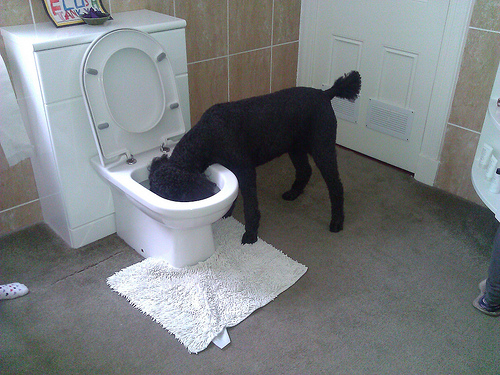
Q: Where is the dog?
A: In bathroom.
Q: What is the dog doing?
A: Drinking.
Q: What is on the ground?
A: Towel.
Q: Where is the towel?
A: On the ground.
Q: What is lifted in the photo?
A: The seat.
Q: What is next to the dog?
A: Door.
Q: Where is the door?
A: Near the dog.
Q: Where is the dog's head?
A: In the toilet.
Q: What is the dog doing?
A: Drinking.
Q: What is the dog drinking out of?
A: Toilet.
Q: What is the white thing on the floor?
A: Rug.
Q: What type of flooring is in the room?
A: Carpet.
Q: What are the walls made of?
A: Tile.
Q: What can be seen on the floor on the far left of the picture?
A: Foot.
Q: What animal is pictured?
A: Dog.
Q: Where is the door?
A: Behind the dog.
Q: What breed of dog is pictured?
A: Poodle.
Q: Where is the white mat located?
A: In front of the toilet.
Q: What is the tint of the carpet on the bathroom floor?
A: Green-gray.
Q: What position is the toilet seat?
A: Upright.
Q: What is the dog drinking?
A: Water from the toilet.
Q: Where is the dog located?
A: In a bathroom.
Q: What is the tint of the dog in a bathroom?
A: Black.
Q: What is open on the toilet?
A: The lid.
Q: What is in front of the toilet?
A: A white rug.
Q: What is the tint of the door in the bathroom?
A: White.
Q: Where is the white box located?
A: Behind a toilet.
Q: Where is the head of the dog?
A: In the toilet.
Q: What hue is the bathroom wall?
A: Brown.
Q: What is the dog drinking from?
A: The toilet.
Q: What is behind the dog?
A: A white door.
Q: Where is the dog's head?
A: In the toilet.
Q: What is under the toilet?
A: A white rug.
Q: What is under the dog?
A: A grey floor.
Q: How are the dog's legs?
A: Black.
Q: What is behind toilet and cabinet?
A: A tan wall.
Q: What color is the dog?
A: Black.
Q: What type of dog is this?
A: Poodle.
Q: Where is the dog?
A: Bathroom.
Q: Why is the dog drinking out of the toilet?
A: He's thirsty.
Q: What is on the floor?
A: A rug.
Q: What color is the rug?
A: White.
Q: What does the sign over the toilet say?
A: Flush.